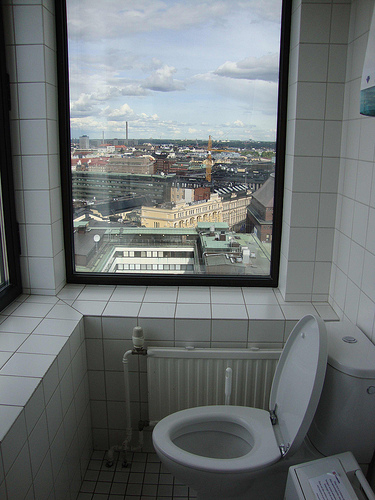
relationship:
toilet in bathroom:
[151, 314, 374, 499] [3, 0, 372, 499]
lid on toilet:
[266, 313, 330, 459] [151, 314, 374, 499]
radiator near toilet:
[104, 327, 284, 469] [151, 314, 374, 499]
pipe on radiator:
[122, 352, 132, 450] [104, 327, 284, 469]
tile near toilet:
[78, 451, 191, 498] [151, 314, 374, 499]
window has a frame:
[72, 3, 271, 276] [56, 0, 295, 287]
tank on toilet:
[311, 323, 374, 479] [151, 314, 374, 499]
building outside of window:
[140, 196, 254, 226] [72, 3, 271, 276]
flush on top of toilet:
[341, 333, 360, 346] [151, 314, 374, 499]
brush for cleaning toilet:
[224, 368, 235, 404] [151, 314, 374, 499]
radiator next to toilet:
[104, 327, 284, 469] [151, 314, 374, 499]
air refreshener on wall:
[359, 12, 375, 116] [332, 0, 374, 340]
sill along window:
[64, 285, 336, 319] [72, 3, 271, 276]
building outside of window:
[124, 118, 132, 157] [72, 3, 271, 276]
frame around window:
[56, 0, 295, 287] [72, 3, 271, 276]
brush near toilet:
[224, 368, 235, 404] [151, 314, 374, 499]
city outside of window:
[77, 122, 270, 265] [72, 3, 271, 276]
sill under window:
[64, 285, 336, 319] [72, 3, 271, 276]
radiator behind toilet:
[104, 327, 284, 469] [151, 314, 374, 499]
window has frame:
[72, 3, 271, 276] [56, 0, 295, 287]